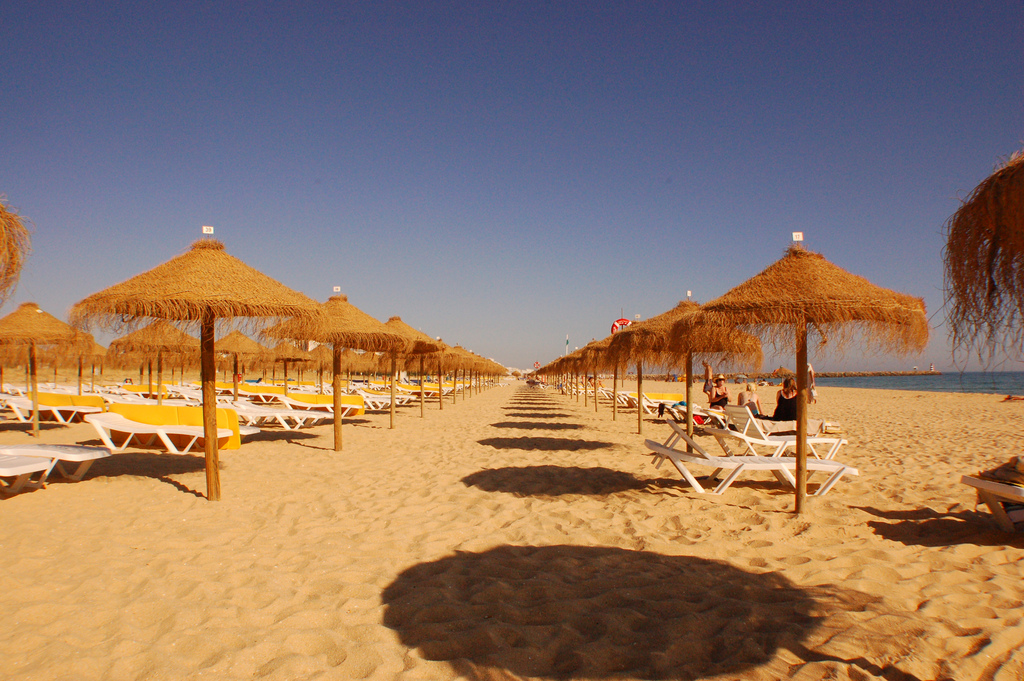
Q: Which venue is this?
A: This is a beach.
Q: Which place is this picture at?
A: It is at the beach.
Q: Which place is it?
A: It is a beach.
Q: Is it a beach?
A: Yes, it is a beach.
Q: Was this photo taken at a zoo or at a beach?
A: It was taken at a beach.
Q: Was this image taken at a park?
A: No, the picture was taken in a beach.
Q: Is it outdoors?
A: Yes, it is outdoors.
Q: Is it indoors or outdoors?
A: It is outdoors.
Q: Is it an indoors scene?
A: No, it is outdoors.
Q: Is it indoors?
A: No, it is outdoors.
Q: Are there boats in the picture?
A: No, there are no boats.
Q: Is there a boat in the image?
A: No, there are no boats.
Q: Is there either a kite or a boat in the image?
A: No, there are no boats or kites.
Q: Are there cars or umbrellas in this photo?
A: Yes, there is an umbrella.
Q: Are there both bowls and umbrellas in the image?
A: No, there is an umbrella but no bowls.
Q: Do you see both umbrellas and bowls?
A: No, there is an umbrella but no bowls.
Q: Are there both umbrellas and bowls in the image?
A: No, there is an umbrella but no bowls.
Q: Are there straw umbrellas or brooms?
A: Yes, there is a straw umbrella.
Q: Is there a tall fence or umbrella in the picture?
A: Yes, there is a tall umbrella.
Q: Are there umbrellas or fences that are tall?
A: Yes, the umbrella is tall.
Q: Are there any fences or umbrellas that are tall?
A: Yes, the umbrella is tall.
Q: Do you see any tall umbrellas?
A: Yes, there is a tall umbrella.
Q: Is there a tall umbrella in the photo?
A: Yes, there is a tall umbrella.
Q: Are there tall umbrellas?
A: Yes, there is a tall umbrella.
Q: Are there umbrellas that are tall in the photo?
A: Yes, there is a tall umbrella.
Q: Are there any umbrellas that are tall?
A: Yes, there is an umbrella that is tall.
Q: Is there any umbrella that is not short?
A: Yes, there is a tall umbrella.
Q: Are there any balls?
A: No, there are no balls.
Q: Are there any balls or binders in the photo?
A: No, there are no balls or binders.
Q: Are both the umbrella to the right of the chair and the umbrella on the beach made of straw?
A: Yes, both the umbrella and the umbrella are made of straw.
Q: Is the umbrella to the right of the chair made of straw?
A: Yes, the umbrella is made of straw.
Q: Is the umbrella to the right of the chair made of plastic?
A: No, the umbrella is made of straw.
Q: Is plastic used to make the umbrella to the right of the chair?
A: No, the umbrella is made of straw.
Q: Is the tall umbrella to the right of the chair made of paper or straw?
A: The umbrella is made of straw.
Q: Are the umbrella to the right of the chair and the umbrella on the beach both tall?
A: Yes, both the umbrella and the umbrella are tall.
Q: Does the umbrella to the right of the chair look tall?
A: Yes, the umbrella is tall.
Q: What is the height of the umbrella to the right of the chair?
A: The umbrella is tall.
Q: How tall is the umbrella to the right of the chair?
A: The umbrella is tall.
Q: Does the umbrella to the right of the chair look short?
A: No, the umbrella is tall.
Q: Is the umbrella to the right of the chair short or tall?
A: The umbrella is tall.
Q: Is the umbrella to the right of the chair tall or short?
A: The umbrella is tall.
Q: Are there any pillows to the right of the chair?
A: No, there is an umbrella to the right of the chair.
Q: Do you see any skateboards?
A: No, there are no skateboards.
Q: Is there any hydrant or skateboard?
A: No, there are no skateboards or fire hydrants.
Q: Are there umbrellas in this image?
A: Yes, there is an umbrella.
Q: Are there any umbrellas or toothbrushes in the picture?
A: Yes, there is an umbrella.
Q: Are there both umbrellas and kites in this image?
A: No, there is an umbrella but no kites.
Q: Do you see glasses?
A: No, there are no glasses.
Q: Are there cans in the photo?
A: No, there are no cans.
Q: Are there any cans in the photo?
A: No, there are no cans.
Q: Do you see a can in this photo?
A: No, there are no cans.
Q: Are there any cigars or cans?
A: No, there are no cans or cigars.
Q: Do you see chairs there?
A: Yes, there is a chair.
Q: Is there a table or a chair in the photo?
A: Yes, there is a chair.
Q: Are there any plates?
A: No, there are no plates.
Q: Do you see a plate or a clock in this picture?
A: No, there are no plates or clocks.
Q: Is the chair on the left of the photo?
A: Yes, the chair is on the left of the image.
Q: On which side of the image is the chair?
A: The chair is on the left of the image.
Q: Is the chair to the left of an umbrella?
A: Yes, the chair is to the left of an umbrella.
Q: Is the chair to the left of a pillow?
A: No, the chair is to the left of an umbrella.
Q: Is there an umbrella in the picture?
A: Yes, there is an umbrella.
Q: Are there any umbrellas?
A: Yes, there is an umbrella.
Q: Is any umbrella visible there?
A: Yes, there is an umbrella.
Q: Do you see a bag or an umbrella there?
A: Yes, there is an umbrella.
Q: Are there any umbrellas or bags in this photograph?
A: Yes, there is an umbrella.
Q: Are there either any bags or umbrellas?
A: Yes, there is an umbrella.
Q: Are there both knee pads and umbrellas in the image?
A: No, there is an umbrella but no knee pads.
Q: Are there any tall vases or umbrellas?
A: Yes, there is a tall umbrella.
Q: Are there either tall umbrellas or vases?
A: Yes, there is a tall umbrella.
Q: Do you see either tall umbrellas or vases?
A: Yes, there is a tall umbrella.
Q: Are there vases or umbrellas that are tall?
A: Yes, the umbrella is tall.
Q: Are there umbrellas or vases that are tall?
A: Yes, the umbrella is tall.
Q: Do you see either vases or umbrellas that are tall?
A: Yes, the umbrella is tall.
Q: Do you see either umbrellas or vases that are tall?
A: Yes, the umbrella is tall.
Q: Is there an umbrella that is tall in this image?
A: Yes, there is a tall umbrella.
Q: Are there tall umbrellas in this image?
A: Yes, there is a tall umbrella.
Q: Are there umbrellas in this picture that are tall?
A: Yes, there is an umbrella that is tall.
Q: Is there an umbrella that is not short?
A: Yes, there is a tall umbrella.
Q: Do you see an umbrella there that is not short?
A: Yes, there is a tall umbrella.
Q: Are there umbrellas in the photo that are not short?
A: Yes, there is a tall umbrella.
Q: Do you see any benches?
A: No, there are no benches.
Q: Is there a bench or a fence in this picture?
A: No, there are no benches or fences.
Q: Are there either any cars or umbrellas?
A: Yes, there is an umbrella.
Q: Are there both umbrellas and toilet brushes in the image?
A: No, there is an umbrella but no toilet brushes.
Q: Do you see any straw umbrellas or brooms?
A: Yes, there is a straw umbrella.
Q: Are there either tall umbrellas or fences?
A: Yes, there is a tall umbrella.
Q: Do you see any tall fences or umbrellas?
A: Yes, there is a tall umbrella.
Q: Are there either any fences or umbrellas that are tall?
A: Yes, the umbrella is tall.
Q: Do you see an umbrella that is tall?
A: Yes, there is a tall umbrella.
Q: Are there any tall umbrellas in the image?
A: Yes, there is a tall umbrella.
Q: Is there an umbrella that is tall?
A: Yes, there is an umbrella that is tall.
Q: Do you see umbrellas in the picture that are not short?
A: Yes, there is a tall umbrella.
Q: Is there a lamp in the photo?
A: No, there are no lamps.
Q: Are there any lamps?
A: No, there are no lamps.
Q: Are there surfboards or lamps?
A: No, there are no lamps or surfboards.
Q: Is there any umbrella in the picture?
A: Yes, there is an umbrella.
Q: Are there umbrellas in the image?
A: Yes, there is an umbrella.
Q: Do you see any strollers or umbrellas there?
A: Yes, there is an umbrella.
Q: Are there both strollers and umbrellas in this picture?
A: No, there is an umbrella but no strollers.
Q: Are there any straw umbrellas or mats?
A: Yes, there is a straw umbrella.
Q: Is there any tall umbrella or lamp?
A: Yes, there is a tall umbrella.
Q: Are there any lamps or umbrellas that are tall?
A: Yes, the umbrella is tall.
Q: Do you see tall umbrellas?
A: Yes, there is a tall umbrella.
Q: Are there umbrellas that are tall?
A: Yes, there is an umbrella that is tall.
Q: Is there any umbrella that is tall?
A: Yes, there is an umbrella that is tall.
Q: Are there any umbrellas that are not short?
A: Yes, there is a tall umbrella.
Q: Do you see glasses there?
A: No, there are no glasses.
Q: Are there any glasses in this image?
A: No, there are no glasses.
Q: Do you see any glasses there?
A: No, there are no glasses.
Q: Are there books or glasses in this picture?
A: No, there are no glasses or books.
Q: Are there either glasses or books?
A: No, there are no glasses or books.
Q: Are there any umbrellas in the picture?
A: Yes, there is an umbrella.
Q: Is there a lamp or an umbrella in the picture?
A: Yes, there is an umbrella.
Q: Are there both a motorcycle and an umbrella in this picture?
A: No, there is an umbrella but no motorcycles.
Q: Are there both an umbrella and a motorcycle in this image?
A: No, there is an umbrella but no motorcycles.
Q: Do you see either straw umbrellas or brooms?
A: Yes, there is a straw umbrella.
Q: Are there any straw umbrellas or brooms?
A: Yes, there is a straw umbrella.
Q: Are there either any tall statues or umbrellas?
A: Yes, there is a tall umbrella.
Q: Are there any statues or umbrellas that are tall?
A: Yes, the umbrella is tall.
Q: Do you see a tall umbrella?
A: Yes, there is a tall umbrella.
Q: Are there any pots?
A: No, there are no pots.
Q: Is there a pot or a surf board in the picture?
A: No, there are no pots or surfboards.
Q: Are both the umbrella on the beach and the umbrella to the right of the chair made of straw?
A: Yes, both the umbrella and the umbrella are made of straw.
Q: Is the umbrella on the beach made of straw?
A: Yes, the umbrella is made of straw.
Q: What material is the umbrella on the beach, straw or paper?
A: The umbrella is made of straw.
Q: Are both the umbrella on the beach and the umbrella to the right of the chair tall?
A: Yes, both the umbrella and the umbrella are tall.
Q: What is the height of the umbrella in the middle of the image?
A: The umbrella is tall.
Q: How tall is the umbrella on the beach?
A: The umbrella is tall.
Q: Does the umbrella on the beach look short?
A: No, the umbrella is tall.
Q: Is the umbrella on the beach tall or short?
A: The umbrella is tall.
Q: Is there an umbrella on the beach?
A: Yes, there is an umbrella on the beach.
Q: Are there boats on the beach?
A: No, there is an umbrella on the beach.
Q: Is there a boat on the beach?
A: No, there is an umbrella on the beach.